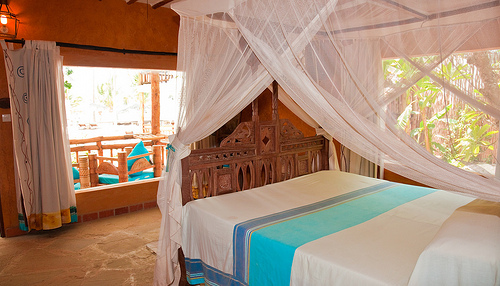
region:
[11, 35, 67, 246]
White curtains pulled back from the window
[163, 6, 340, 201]
wooden frame at the foot of the bed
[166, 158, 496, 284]
queen sized bed in the room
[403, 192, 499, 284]
white pillows on the bed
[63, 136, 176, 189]
wooden chairs outside the window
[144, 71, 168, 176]
large wooden post outside the window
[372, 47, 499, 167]
green plants outside the window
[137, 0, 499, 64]
black metal frame over the bed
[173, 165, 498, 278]
blue and white sheets on the bed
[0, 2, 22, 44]
light over the white curtain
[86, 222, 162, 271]
white square spot on carpet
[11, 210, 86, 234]
yellow end of the drapes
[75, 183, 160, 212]
wooden base of opening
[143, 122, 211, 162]
white sheer bed curtain holder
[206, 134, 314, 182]
wooden frame on canopy bed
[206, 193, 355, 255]
white blue and green sheet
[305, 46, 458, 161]
sheer cover over top of the bed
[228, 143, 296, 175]
decorative design in the bed head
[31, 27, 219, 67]
black curtain rod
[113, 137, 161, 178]
blue pillow on hammock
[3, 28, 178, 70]
Black curtain rod above window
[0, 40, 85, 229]
Large curtain on black curtain rod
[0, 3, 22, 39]
Light above black curtain rod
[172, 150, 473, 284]
White and blue sheet on bed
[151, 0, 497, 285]
Clear white tapestry above bed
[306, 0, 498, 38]
Black metal bar holding tapestry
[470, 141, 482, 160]
Large leaf is green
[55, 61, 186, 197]
Large window in front of bed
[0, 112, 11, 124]
Light switch plate next to curtain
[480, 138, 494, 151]
Leaf is large and green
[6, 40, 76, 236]
cutains hanging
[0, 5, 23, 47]
a light that is turned on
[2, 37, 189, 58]
A long black curtain rod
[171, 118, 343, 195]
the foot of a bed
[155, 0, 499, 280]
a four poster bed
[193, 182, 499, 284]
A white comforter with a blue stripe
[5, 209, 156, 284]
A floor made out of rock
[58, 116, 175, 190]
an outside patio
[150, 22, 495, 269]
netting curtins draped over a four poster bed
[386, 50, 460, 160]
A tree with green leafs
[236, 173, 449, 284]
light blue section of blanket on the bed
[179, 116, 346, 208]
foot of the bed frame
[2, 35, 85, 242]
white curtain pulled to the side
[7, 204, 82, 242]
gold and blue at the bottom of the curtain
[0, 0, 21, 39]
lamp on the ceiling in the corner of the room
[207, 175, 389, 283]
dark blue section of the bed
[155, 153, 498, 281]
a made bed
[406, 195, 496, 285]
white pillow on the bed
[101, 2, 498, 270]
white curtain over the bed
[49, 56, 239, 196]
a window outside